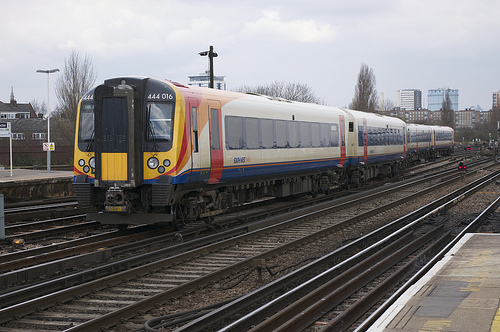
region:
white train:
[61, 62, 443, 187]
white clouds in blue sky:
[5, 6, 53, 81]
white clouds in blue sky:
[98, 16, 128, 66]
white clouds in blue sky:
[131, 21, 175, 73]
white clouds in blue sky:
[228, 16, 270, 80]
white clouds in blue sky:
[288, 28, 325, 80]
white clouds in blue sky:
[370, 22, 430, 63]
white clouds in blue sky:
[418, 6, 465, 64]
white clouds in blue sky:
[268, 16, 312, 73]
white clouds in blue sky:
[380, 12, 472, 73]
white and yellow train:
[58, 68, 488, 192]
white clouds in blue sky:
[14, 8, 58, 40]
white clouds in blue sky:
[412, 8, 450, 38]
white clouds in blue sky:
[390, 26, 445, 71]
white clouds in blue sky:
[281, 33, 311, 61]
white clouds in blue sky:
[87, 32, 139, 49]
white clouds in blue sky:
[445, 18, 479, 59]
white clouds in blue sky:
[238, 11, 280, 43]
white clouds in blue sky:
[94, 2, 152, 30]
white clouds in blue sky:
[17, 19, 74, 43]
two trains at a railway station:
[63, 69, 460, 236]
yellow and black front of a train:
[66, 72, 189, 231]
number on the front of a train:
[141, 88, 176, 101]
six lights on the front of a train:
[75, 151, 173, 176]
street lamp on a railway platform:
[32, 65, 66, 171]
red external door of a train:
[204, 95, 227, 192]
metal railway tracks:
[2, 153, 498, 328]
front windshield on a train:
[141, 93, 176, 143]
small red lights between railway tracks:
[446, 159, 476, 194]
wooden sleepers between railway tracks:
[102, 249, 210, 304]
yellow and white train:
[71, 65, 465, 187]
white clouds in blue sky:
[147, 13, 191, 85]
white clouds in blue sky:
[261, 29, 303, 80]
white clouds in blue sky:
[410, 1, 441, 51]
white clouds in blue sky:
[224, 33, 299, 90]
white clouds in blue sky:
[81, 21, 123, 46]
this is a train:
[66, 27, 303, 265]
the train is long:
[135, 105, 345, 234]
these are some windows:
[208, 64, 307, 172]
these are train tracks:
[273, 313, 312, 325]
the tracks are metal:
[215, 207, 278, 315]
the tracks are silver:
[86, 253, 173, 317]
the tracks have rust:
[169, 313, 206, 328]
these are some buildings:
[389, 71, 461, 136]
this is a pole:
[12, 40, 80, 142]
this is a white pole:
[21, 62, 153, 287]